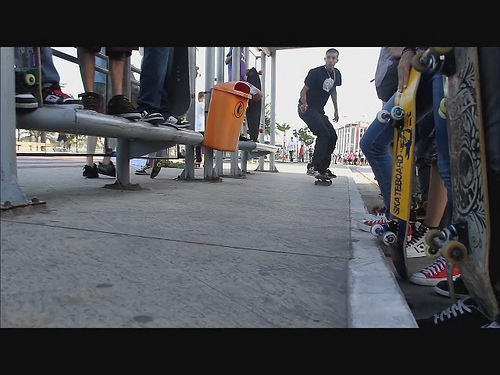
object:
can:
[206, 79, 255, 155]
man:
[298, 48, 344, 179]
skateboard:
[312, 174, 335, 187]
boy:
[357, 48, 459, 285]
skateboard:
[370, 64, 426, 284]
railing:
[1, 46, 286, 209]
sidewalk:
[5, 164, 349, 328]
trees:
[293, 126, 315, 164]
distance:
[271, 45, 387, 163]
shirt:
[296, 66, 345, 112]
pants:
[296, 104, 339, 171]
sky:
[274, 47, 383, 129]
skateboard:
[410, 48, 500, 317]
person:
[71, 42, 145, 120]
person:
[137, 45, 190, 129]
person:
[12, 41, 83, 113]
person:
[373, 44, 439, 257]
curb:
[347, 166, 420, 327]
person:
[416, 47, 500, 331]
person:
[359, 45, 462, 284]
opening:
[233, 79, 254, 96]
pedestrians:
[342, 149, 354, 167]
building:
[335, 114, 376, 165]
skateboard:
[392, 151, 407, 217]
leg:
[108, 58, 126, 95]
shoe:
[105, 92, 144, 120]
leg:
[77, 51, 97, 93]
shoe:
[75, 91, 102, 117]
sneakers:
[408, 259, 462, 285]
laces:
[433, 297, 471, 325]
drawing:
[449, 48, 484, 291]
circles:
[457, 150, 475, 189]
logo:
[393, 112, 413, 217]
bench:
[3, 107, 277, 205]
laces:
[113, 94, 134, 112]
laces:
[80, 91, 101, 109]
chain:
[324, 66, 340, 82]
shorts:
[73, 48, 134, 58]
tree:
[276, 121, 290, 162]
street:
[351, 161, 385, 211]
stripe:
[353, 164, 382, 202]